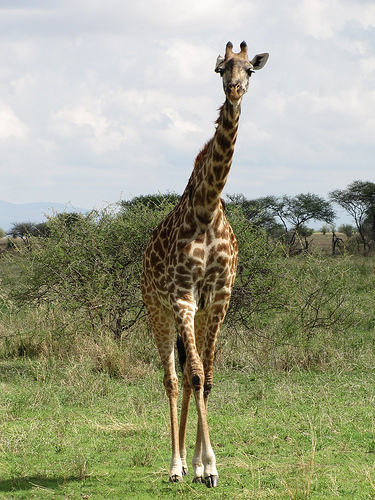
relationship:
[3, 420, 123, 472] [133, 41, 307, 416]
grass near giraffe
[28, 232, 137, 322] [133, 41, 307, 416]
trees behind giraffe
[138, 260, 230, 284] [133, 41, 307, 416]
spots on giraffe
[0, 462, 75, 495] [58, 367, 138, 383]
shadow on ground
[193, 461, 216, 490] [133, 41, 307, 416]
feet of giraffe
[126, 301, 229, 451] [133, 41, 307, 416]
legs of giraffe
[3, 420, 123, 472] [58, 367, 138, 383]
grass on ground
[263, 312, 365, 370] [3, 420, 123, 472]
weeds in grass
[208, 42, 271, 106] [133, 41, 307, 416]
head of giraffe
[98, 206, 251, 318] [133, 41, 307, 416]
body of giraffe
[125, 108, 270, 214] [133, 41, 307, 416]
neck of giraffe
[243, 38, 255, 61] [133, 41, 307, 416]
horns of giraffe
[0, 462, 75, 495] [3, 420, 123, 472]
shadow on grass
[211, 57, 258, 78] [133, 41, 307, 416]
eyes of giraffe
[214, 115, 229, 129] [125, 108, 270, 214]
hair on neck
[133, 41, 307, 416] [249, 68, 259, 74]
giraffe has eyelashes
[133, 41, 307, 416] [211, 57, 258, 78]
giraffe has eyes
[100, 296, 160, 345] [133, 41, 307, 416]
tail of giraffe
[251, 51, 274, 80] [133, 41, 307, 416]
ear of giraffe